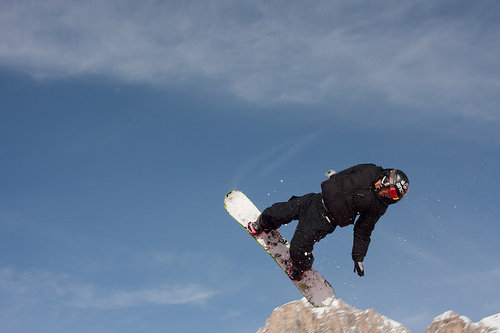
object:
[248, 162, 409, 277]
man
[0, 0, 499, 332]
sky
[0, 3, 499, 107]
cloud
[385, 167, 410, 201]
helmet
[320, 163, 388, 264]
jacket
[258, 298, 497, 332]
mountain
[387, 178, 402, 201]
goggles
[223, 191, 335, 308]
snowboard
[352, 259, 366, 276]
glove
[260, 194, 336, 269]
pants